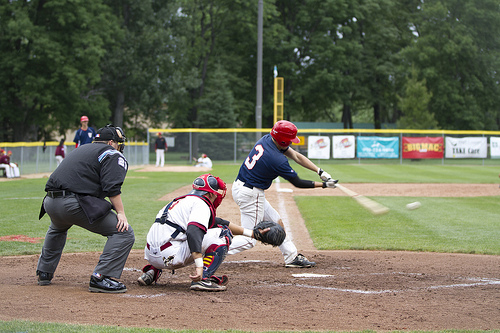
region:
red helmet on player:
[264, 114, 299, 145]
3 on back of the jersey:
[245, 136, 262, 177]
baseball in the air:
[404, 194, 425, 214]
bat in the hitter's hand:
[326, 179, 387, 217]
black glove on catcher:
[256, 220, 284, 248]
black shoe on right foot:
[281, 254, 322, 267]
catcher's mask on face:
[193, 171, 225, 202]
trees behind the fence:
[1, 4, 127, 94]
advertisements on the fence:
[312, 135, 496, 161]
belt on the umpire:
[38, 187, 81, 201]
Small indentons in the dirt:
[20, 286, 56, 311]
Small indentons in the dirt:
[72, 295, 126, 321]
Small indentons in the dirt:
[150, 298, 207, 325]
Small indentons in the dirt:
[233, 294, 313, 318]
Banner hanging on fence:
[307, 131, 334, 168]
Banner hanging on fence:
[324, 129, 349, 164]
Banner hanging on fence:
[355, 127, 399, 164]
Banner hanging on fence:
[393, 130, 439, 166]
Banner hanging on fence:
[443, 132, 485, 160]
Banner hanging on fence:
[490, 131, 497, 154]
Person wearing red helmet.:
[275, 108, 309, 148]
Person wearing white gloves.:
[313, 163, 350, 216]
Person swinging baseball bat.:
[313, 157, 355, 215]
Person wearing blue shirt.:
[245, 136, 293, 193]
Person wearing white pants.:
[247, 193, 274, 220]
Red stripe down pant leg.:
[246, 195, 266, 222]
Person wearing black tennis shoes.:
[289, 253, 318, 273]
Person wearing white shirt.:
[166, 203, 201, 225]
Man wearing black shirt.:
[53, 143, 117, 185]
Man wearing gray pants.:
[31, 213, 113, 246]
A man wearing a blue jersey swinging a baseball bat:
[232, 120, 387, 265]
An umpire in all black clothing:
[36, 125, 133, 292]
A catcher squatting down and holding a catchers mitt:
[141, 173, 286, 294]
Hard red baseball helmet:
[268, 119, 306, 143]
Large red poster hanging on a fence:
[401, 133, 446, 160]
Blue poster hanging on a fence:
[355, 135, 400, 161]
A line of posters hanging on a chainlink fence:
[306, 133, 499, 160]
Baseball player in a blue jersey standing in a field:
[73, 115, 99, 148]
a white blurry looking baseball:
[403, 199, 422, 210]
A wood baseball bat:
[327, 176, 390, 213]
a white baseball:
[408, 200, 420, 212]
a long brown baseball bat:
[332, 180, 389, 218]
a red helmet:
[270, 120, 300, 142]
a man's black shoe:
[88, 273, 126, 293]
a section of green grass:
[295, 193, 497, 254]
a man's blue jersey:
[239, 124, 296, 188]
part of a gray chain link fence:
[150, 128, 250, 162]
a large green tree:
[381, 0, 498, 125]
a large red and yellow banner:
[401, 137, 445, 158]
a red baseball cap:
[78, 113, 91, 122]